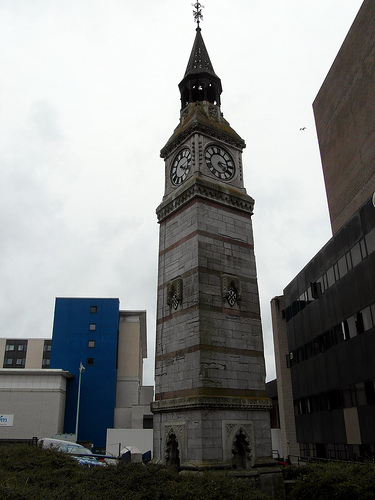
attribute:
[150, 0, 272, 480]
stone spire — tall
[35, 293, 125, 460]
wall — blue , rectangle 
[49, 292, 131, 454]
wall — blue 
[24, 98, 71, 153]
clouds — thick 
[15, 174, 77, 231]
clouds — thick 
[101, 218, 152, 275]
clouds — thick 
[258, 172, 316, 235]
clouds — thick 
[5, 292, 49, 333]
clouds — thick 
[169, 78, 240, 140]
roof — brown 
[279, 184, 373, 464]
building — brown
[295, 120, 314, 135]
small bird — small 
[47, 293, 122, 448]
wall — blue 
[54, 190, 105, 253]
skies — gray , overcast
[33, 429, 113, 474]
vehicle — blue 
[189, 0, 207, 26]
weather vane — metal 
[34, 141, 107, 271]
sky — overcast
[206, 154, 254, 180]
hands — black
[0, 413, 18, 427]
sign — white 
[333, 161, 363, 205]
panel — brown 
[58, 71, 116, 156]
sky — overcast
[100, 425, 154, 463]
wall — beige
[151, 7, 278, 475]
tower — gray, brick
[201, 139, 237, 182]
clock — round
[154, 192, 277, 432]
wall — stone , brick  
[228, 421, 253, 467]
arch — alternating colors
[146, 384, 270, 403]
stripe — Brown 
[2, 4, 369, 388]
sky — overcast, cloudy, grey